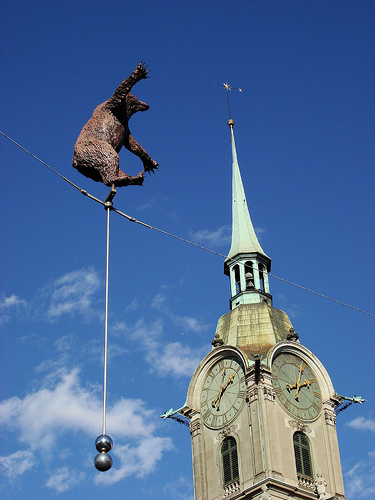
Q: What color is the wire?
A: Gray.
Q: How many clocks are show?
A: Two.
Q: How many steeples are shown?
A: One.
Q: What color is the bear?
A: Brown.